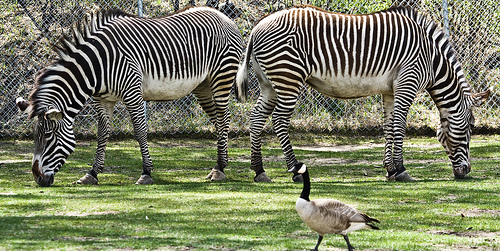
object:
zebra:
[234, 7, 486, 192]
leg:
[250, 88, 273, 183]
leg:
[271, 93, 309, 184]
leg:
[375, 100, 397, 187]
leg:
[392, 85, 413, 181]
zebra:
[14, 2, 247, 193]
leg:
[78, 104, 111, 184]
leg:
[126, 100, 157, 186]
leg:
[197, 87, 217, 115]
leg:
[209, 70, 235, 182]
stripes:
[321, 27, 404, 69]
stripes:
[142, 30, 206, 73]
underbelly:
[318, 70, 388, 103]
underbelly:
[143, 76, 202, 109]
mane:
[381, 6, 481, 117]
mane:
[45, 4, 134, 51]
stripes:
[421, 6, 481, 89]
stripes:
[61, 26, 100, 58]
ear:
[13, 96, 36, 119]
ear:
[42, 107, 67, 124]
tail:
[232, 34, 255, 108]